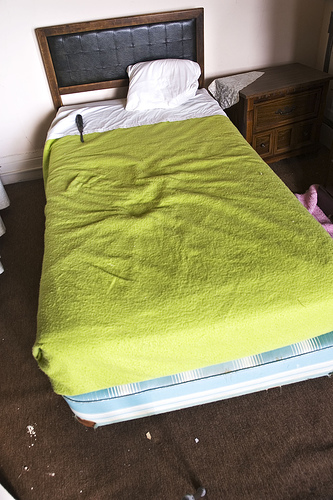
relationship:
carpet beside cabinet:
[1, 147, 332, 497] [214, 61, 330, 163]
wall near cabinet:
[2, 3, 325, 169] [214, 61, 330, 163]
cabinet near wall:
[214, 61, 330, 163] [2, 3, 325, 169]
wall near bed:
[2, 3, 325, 169] [24, 98, 328, 418]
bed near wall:
[24, 98, 328, 418] [2, 3, 325, 169]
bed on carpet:
[24, 98, 328, 418] [1, 147, 332, 497]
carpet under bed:
[1, 147, 332, 497] [24, 98, 328, 418]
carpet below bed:
[1, 147, 332, 497] [24, 98, 328, 418]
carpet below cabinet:
[1, 147, 332, 497] [214, 61, 330, 163]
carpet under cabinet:
[1, 147, 332, 497] [214, 61, 330, 163]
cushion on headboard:
[45, 15, 198, 89] [30, 3, 219, 104]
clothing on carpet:
[289, 178, 322, 241] [1, 147, 332, 497]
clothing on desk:
[207, 62, 268, 120] [214, 58, 322, 176]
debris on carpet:
[22, 419, 208, 494] [1, 177, 319, 498]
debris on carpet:
[2, 408, 222, 494] [1, 177, 319, 498]